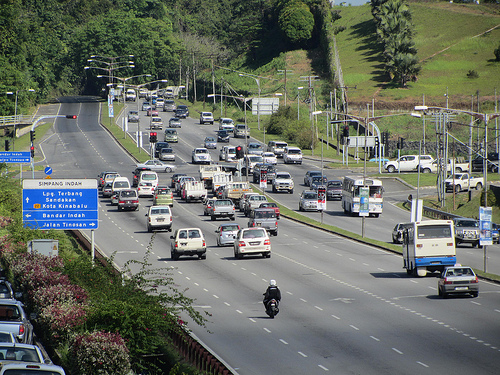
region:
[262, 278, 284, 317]
A motorcyle rider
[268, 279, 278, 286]
A white helmet on the rider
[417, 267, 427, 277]
A rear white flap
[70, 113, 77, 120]
A red intersection light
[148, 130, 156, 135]
A pair of red intersection lights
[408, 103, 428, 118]
Two raised street lamps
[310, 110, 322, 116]
A white street lamp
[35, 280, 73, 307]
A hedge with flowers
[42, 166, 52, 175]
A blue traffic sign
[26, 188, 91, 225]
An information sign with a blue base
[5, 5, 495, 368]
This is a highway scene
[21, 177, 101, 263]
A highway sign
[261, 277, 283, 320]
This person is riding a motorcycle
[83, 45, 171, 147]
A row of street lights are in the middle of the highway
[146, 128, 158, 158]
A traffic light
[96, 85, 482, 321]
Vehicle traffic is on the highway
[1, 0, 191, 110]
Trees are growing near the highway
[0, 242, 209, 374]
Bushes are growing along the highway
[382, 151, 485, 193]
These vehicles are waiting to enter the highway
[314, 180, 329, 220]
A banner is hanging on the light post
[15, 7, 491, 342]
many cars on the road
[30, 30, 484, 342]
vehicles at a busy intersection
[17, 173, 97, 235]
large blue road sign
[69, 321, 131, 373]
low red and green bush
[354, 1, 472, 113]
line of trees on hillside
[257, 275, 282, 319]
person riding a motorcyle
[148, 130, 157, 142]
black traffic signal with a red light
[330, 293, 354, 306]
faded white directional arrow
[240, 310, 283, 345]
white painted lane lines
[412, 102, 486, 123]
over hanging street light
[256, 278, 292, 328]
Man on a motorcycle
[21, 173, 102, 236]
Blue traffic sign on a highway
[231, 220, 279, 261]
White jeep on a highway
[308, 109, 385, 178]
Street light on a corner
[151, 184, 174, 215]
Green jeep on a highway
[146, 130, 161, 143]
Traffic light showing red light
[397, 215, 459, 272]
white and blue bus on highway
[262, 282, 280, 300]
Man wearing a black jacket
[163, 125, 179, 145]
Green automobile on a highway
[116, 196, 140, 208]
Car with red lights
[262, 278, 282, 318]
back of a man on a motorcycle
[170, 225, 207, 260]
white car on the street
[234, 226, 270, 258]
white suv on the street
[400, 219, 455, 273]
large white and blue truck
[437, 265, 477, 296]
small white car on the street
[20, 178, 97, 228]
a blue and white sign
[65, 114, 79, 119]
a stop light showing red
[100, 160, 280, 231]
a lot of cars on the road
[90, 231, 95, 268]
a thin metal pole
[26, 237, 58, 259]
a grey metal box